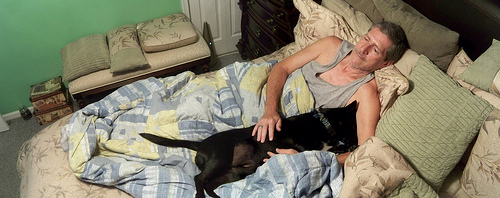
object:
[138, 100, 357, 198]
dog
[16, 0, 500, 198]
bed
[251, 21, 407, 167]
man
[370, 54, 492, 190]
pillow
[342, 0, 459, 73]
pillow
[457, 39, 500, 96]
pillow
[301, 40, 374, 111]
tank top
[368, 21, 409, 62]
hair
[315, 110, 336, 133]
collar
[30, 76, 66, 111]
box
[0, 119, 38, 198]
floor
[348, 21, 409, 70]
head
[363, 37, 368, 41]
eye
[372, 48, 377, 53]
eye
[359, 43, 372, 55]
nose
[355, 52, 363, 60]
mouth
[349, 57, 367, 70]
chin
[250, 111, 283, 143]
hand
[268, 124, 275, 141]
finger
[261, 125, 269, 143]
finger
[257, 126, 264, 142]
finger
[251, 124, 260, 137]
finger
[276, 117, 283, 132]
finger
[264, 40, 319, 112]
arm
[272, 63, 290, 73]
elbow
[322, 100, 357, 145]
head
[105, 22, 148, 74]
cushion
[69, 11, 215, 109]
chair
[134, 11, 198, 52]
cushion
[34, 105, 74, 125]
box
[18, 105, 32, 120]
jar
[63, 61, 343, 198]
blanket